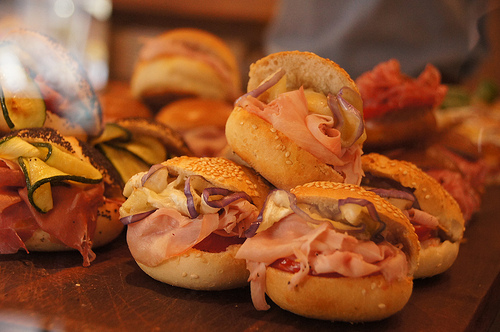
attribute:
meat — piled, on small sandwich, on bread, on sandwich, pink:
[255, 86, 348, 150]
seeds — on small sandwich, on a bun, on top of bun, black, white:
[180, 154, 254, 185]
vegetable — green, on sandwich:
[12, 141, 106, 200]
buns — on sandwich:
[168, 156, 397, 235]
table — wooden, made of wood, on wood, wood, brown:
[2, 267, 175, 331]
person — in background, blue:
[300, 4, 496, 77]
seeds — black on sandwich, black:
[37, 125, 70, 144]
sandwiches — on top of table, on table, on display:
[116, 50, 467, 323]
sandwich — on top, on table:
[220, 45, 393, 204]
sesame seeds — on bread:
[184, 155, 240, 177]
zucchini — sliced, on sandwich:
[96, 129, 155, 169]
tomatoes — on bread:
[365, 64, 446, 105]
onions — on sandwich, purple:
[182, 176, 240, 214]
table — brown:
[440, 221, 481, 323]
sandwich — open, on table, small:
[5, 131, 122, 255]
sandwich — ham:
[125, 151, 249, 280]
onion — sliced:
[279, 187, 389, 230]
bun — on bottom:
[265, 269, 412, 318]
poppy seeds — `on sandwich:
[32, 131, 68, 143]